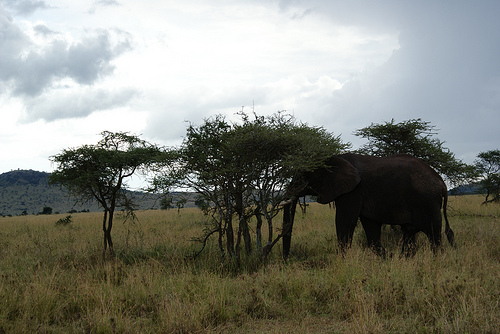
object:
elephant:
[273, 154, 457, 264]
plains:
[0, 183, 500, 324]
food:
[279, 260, 284, 265]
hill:
[0, 164, 260, 219]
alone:
[279, 151, 463, 261]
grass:
[0, 193, 499, 333]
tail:
[442, 192, 456, 244]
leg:
[336, 214, 351, 245]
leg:
[367, 224, 377, 248]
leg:
[408, 233, 414, 252]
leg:
[423, 223, 447, 254]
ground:
[0, 178, 500, 331]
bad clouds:
[0, 3, 401, 195]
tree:
[52, 130, 174, 259]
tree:
[161, 105, 342, 263]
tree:
[352, 117, 477, 173]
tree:
[476, 146, 498, 204]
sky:
[0, 0, 499, 199]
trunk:
[278, 185, 301, 264]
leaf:
[139, 139, 146, 144]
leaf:
[130, 216, 137, 221]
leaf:
[74, 189, 79, 196]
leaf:
[100, 143, 103, 149]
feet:
[339, 249, 354, 260]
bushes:
[43, 129, 165, 257]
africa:
[0, 0, 497, 331]